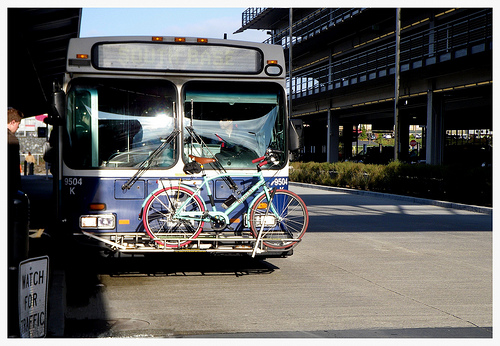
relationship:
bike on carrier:
[139, 154, 311, 250] [79, 230, 301, 257]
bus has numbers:
[52, 33, 305, 259] [63, 176, 84, 196]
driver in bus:
[215, 114, 239, 151] [52, 33, 305, 259]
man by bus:
[7, 104, 22, 203] [52, 33, 305, 259]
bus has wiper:
[52, 33, 305, 259] [120, 99, 179, 191]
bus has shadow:
[52, 33, 305, 259] [63, 252, 279, 276]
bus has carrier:
[52, 33, 305, 259] [79, 230, 301, 257]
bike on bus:
[139, 154, 311, 250] [52, 33, 305, 259]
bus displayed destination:
[52, 33, 305, 259] [97, 40, 262, 76]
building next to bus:
[237, 7, 491, 181] [52, 33, 305, 259]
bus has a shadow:
[52, 33, 305, 259] [63, 252, 279, 276]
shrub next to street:
[290, 158, 445, 200] [68, 180, 494, 337]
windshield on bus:
[65, 79, 287, 171] [52, 33, 305, 259]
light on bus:
[81, 215, 99, 229] [52, 33, 305, 259]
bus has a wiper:
[52, 33, 305, 259] [120, 99, 179, 191]